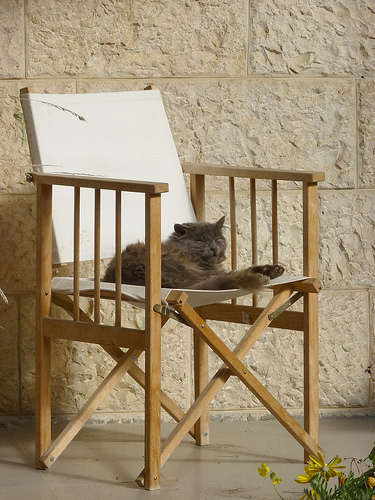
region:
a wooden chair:
[4, 75, 358, 495]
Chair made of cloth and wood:
[8, 72, 320, 486]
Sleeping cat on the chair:
[99, 194, 292, 309]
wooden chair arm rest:
[22, 161, 171, 357]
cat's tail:
[154, 255, 271, 294]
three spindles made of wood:
[223, 181, 288, 262]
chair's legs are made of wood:
[19, 321, 331, 495]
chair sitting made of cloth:
[162, 273, 309, 312]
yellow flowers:
[240, 445, 341, 492]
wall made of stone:
[266, 42, 365, 138]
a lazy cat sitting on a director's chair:
[79, 179, 312, 347]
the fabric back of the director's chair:
[17, 87, 194, 243]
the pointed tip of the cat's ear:
[209, 211, 235, 225]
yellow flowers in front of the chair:
[252, 443, 357, 491]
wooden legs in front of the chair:
[116, 437, 185, 493]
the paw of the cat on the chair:
[253, 257, 290, 284]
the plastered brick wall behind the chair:
[214, 68, 371, 159]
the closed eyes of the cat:
[193, 230, 226, 248]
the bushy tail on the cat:
[198, 270, 271, 292]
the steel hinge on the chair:
[259, 288, 321, 323]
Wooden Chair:
[10, 83, 338, 491]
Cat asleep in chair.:
[100, 213, 285, 290]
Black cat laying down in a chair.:
[102, 214, 285, 292]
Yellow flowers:
[258, 448, 374, 498]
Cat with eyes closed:
[102, 212, 285, 289]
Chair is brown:
[19, 89, 330, 485]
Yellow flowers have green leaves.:
[250, 456, 373, 498]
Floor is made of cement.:
[5, 469, 118, 496]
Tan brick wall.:
[208, 7, 360, 162]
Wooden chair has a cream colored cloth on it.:
[16, 80, 198, 268]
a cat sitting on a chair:
[13, 78, 351, 493]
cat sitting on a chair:
[15, 77, 348, 492]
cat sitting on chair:
[12, 73, 336, 497]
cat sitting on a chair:
[13, 75, 332, 493]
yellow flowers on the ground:
[266, 462, 373, 486]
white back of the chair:
[28, 107, 196, 224]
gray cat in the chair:
[133, 231, 259, 275]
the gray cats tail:
[148, 272, 259, 300]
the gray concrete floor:
[174, 466, 274, 497]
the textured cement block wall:
[208, 95, 342, 156]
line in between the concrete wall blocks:
[31, 74, 364, 78]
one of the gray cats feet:
[252, 263, 289, 276]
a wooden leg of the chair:
[145, 278, 158, 452]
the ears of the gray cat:
[176, 218, 236, 235]